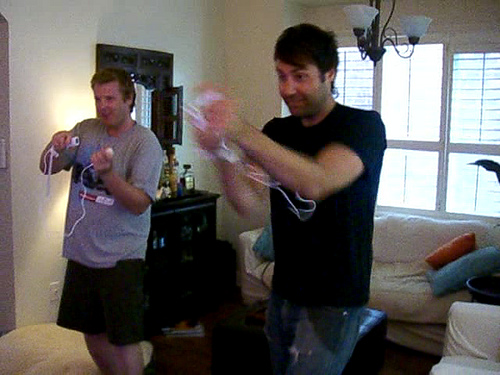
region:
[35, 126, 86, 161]
Wii remote in the hand.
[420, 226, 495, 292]
Pillows on the couch.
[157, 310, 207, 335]
Books on the floor.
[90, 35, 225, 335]
Cabinet against the wall.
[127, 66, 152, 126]
Mirror on the cabinet.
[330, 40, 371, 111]
Blinds on the window.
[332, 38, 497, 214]
Window in the wall.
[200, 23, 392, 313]
Man in black shirt.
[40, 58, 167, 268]
Man in gray shirt.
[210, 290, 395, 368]
Ottoman behind the man.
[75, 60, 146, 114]
man has brown hair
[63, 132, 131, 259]
man has grey shirt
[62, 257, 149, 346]
man has black shorts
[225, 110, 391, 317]
boy has black shirt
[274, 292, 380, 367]
boy has blue pants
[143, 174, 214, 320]
black chest behind men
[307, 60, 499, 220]
white frame on wall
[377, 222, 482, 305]
white sofa behind boys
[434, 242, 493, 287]
blue cushions on sofa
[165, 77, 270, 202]
boy holds Wii controllers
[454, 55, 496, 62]
white plastic window blind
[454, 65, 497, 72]
white plastic window blind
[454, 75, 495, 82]
white plastic window blind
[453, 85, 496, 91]
white plastic window blind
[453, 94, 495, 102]
white plastic window blind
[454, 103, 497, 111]
white plastic window blind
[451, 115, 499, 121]
white plastic window blind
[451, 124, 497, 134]
white plastic window blind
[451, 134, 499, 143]
white plastic window blind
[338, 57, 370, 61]
white plastic window blind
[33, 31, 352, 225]
two men holding game controllers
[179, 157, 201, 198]
a glass bottle of alcohol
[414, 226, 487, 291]
a blue and orange pillows on a couch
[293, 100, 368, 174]
a man wearing a black shirt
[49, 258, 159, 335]
a man wearing black shorts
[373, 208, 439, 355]
a white couch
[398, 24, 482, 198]
a window covered with a blind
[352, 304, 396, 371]
a black foot stool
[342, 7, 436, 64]
a light hanging from the cieling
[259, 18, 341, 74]
a man with black hair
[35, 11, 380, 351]
men are playing video game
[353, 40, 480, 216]
the windows are bright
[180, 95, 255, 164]
the hands are blurred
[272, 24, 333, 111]
head of the man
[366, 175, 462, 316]
couch in the back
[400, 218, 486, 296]
cushions on the couch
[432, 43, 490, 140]
shades on the window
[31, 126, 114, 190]
controllers in the hands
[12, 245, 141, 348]
shorts on the man